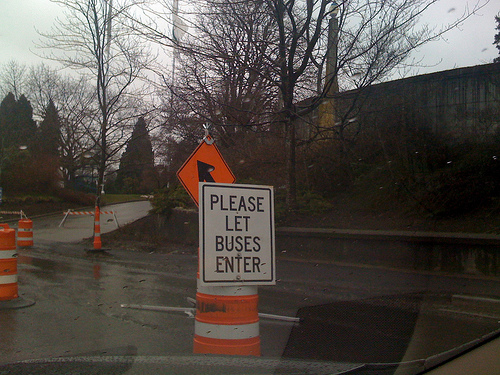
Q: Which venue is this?
A: This is a street.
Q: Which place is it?
A: It is a street.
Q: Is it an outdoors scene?
A: Yes, it is outdoors.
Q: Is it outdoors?
A: Yes, it is outdoors.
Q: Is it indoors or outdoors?
A: It is outdoors.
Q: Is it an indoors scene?
A: No, it is outdoors.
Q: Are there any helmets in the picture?
A: No, there are no helmets.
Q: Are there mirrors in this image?
A: No, there are no mirrors.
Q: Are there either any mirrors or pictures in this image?
A: No, there are no mirrors or pictures.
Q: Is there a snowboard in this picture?
A: No, there are no snowboards.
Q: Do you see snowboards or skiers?
A: No, there are no snowboards or skiers.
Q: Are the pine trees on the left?
A: Yes, the pine trees are on the left of the image.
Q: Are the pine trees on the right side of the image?
A: No, the pine trees are on the left of the image.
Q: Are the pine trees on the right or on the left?
A: The pine trees are on the left of the image.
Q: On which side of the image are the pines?
A: The pines are on the left of the image.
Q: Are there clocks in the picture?
A: No, there are no clocks.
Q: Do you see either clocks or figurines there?
A: No, there are no clocks or figurines.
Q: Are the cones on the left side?
A: Yes, the cones are on the left of the image.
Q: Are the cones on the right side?
A: No, the cones are on the left of the image.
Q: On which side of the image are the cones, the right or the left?
A: The cones are on the left of the image.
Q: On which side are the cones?
A: The cones are on the left of the image.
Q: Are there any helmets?
A: No, there are no helmets.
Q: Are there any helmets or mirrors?
A: No, there are no helmets or mirrors.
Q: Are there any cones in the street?
A: Yes, there is a cone in the street.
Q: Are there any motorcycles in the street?
A: No, there is a cone in the street.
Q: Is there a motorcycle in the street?
A: No, there is a cone in the street.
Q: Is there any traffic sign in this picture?
A: Yes, there is a traffic sign.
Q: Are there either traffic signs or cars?
A: Yes, there is a traffic sign.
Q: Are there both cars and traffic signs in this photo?
A: No, there is a traffic sign but no cars.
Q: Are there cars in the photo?
A: No, there are no cars.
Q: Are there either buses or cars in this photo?
A: No, there are no cars or buses.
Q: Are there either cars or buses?
A: No, there are no cars or buses.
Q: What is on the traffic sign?
A: The arrow is on the traffic sign.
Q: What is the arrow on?
A: The arrow is on the traffic sign.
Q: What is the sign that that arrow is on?
A: The sign is a traffic sign.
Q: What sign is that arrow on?
A: The arrow is on the traffic sign.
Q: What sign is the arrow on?
A: The arrow is on the traffic sign.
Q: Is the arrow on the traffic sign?
A: Yes, the arrow is on the traffic sign.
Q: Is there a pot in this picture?
A: No, there are no pots.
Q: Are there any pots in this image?
A: No, there are no pots.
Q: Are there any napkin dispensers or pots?
A: No, there are no pots or napkin dispensers.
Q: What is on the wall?
A: The light post is on the wall.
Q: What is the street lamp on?
A: The street lamp is on the wall.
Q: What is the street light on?
A: The street lamp is on the wall.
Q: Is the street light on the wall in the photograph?
A: Yes, the street light is on the wall.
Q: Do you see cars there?
A: No, there are no cars.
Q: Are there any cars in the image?
A: No, there are no cars.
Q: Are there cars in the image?
A: No, there are no cars.